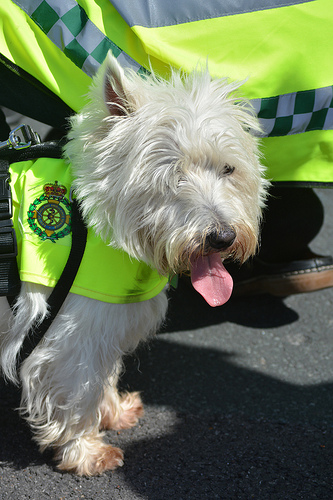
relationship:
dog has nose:
[0, 47, 273, 478] [200, 222, 240, 254]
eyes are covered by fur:
[151, 149, 243, 195] [157, 173, 170, 192]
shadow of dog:
[102, 328, 322, 495] [0, 47, 273, 478]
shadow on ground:
[102, 328, 322, 495] [188, 309, 321, 494]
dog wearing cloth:
[14, 58, 290, 489] [11, 139, 163, 309]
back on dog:
[7, 150, 180, 324] [14, 58, 290, 489]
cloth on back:
[11, 139, 163, 309] [7, 150, 180, 324]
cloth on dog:
[11, 139, 163, 309] [14, 58, 290, 489]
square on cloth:
[273, 89, 297, 116] [0, 1, 333, 188]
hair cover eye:
[126, 132, 199, 208] [159, 157, 184, 177]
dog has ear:
[0, 47, 273, 478] [93, 43, 147, 113]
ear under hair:
[219, 91, 238, 107] [183, 58, 268, 137]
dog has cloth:
[0, 47, 273, 478] [7, 151, 170, 308]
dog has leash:
[0, 47, 273, 478] [3, 144, 64, 160]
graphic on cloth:
[26, 181, 82, 248] [7, 151, 170, 308]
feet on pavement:
[48, 382, 149, 481] [8, 279, 319, 493]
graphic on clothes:
[22, 181, 82, 243] [8, 156, 170, 305]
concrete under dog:
[210, 393, 280, 491] [0, 47, 273, 478]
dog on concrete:
[0, 47, 273, 478] [210, 393, 280, 491]